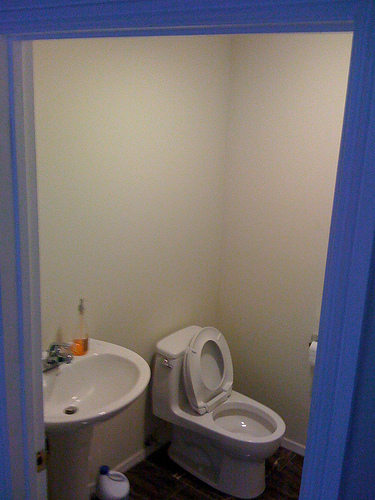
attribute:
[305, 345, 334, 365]
roll — white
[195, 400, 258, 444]
bowl — white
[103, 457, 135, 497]
container — white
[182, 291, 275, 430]
toilet — white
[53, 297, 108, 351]
container — clear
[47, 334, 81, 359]
handle — silver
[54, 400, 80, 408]
drain — silver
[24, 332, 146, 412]
sink — white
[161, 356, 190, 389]
plunger — silver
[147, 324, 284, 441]
toilet — white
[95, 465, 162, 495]
bottle — white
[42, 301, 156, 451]
sink — white, tall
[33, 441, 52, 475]
door jamb — golden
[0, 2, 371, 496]
door frame — blue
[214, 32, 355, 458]
walls — white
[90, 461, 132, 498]
liquid bottle — white, blue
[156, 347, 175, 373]
apparatus — silver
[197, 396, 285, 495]
toilet bowl — clean, white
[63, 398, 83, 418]
drain — silver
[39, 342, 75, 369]
faucet — silver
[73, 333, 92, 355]
soap — orange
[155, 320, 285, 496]
porcelain toilet — white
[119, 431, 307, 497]
floor — dark, tiled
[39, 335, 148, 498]
bathroom sink — white, porcelain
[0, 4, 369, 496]
door trim — blue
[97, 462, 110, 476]
cap — blue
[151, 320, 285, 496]
toilet — porcelain, white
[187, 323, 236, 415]
seat — up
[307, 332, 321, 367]
paper — toilet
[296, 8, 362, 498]
curtain — blue, shower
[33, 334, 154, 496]
sink — small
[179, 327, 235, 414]
lid — toilet, lifted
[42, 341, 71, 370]
faucet — chrome, sink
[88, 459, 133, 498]
bleach bottle — white, plastic